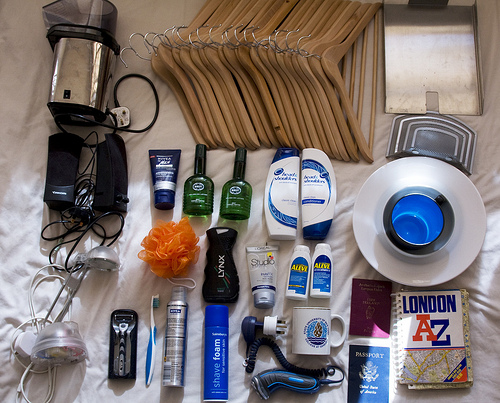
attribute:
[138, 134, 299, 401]
toiletries — personal, hygenic, varied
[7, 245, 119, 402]
facial lamp — small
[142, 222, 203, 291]
sponge — bright, orange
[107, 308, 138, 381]
razor — black, silver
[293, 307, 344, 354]
mug — personal, favorite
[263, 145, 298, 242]
bottles — shampoo filled, Head & Shoulders branded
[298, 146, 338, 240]
bottles — shampoo filled, Head & Shoulders branded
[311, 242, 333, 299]
pain medication — over-the-counter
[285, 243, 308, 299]
pain medication — over-the-counter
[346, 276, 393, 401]
documents — necessary, travel related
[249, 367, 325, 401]
shaver — electric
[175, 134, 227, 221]
polish — green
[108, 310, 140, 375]
razor — handheld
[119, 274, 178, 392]
toothbrush — white, blue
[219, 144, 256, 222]
nail polish — green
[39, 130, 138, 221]
speakers — small, stereo, music kind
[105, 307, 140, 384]
shaving razor — black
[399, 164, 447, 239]
cup — blue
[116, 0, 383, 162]
hangers — wooden, closet, garment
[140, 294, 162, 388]
tooth brush — white and blue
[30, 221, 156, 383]
lamp — high intensity, office style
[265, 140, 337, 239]
shampoo — conditioning, Head and Shoulders branded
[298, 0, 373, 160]
hanger — wooden, v-neck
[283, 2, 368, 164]
hanger — wooden, v-neck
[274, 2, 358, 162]
hanger — wooden, v-neck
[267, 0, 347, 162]
hanger — wooden, v-neck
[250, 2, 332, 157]
hanger — wooden, v-neck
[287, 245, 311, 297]
bottle — short, white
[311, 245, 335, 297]
bottle — short, white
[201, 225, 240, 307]
bottle — black